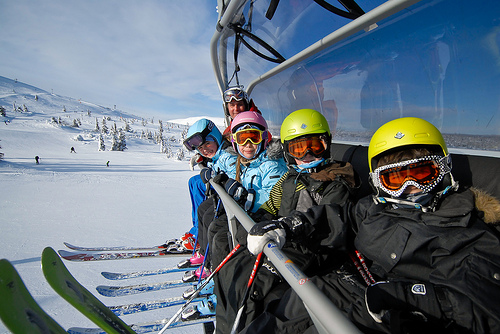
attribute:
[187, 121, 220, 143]
helmet — blue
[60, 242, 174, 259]
ski poles — white, black, red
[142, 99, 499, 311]
people — having fun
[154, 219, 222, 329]
boots — pink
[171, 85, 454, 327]
people — happy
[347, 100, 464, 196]
helmet — yellow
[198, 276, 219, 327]
boot — blue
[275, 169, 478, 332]
jacket — black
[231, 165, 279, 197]
jacket — blue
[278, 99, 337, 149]
helmet — lime green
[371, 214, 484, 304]
jacket — black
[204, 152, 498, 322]
clothing — warm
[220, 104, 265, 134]
helmet — pink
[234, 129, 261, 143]
goggles — framed, yellow